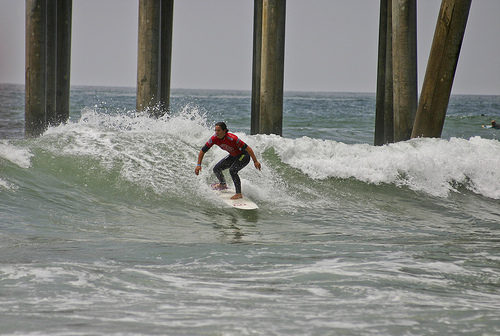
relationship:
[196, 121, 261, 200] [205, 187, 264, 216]
surfer on surfboard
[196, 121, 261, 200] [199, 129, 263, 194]
surfer in wetsuit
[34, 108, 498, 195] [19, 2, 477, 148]
waves under pier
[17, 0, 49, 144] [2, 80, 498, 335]
pole in water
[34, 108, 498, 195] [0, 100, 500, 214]
waves have waves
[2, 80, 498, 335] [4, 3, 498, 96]
water meets sky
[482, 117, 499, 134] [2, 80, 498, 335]
surfer in water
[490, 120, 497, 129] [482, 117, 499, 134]
head of surfer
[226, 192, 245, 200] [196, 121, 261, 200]
foot of surfer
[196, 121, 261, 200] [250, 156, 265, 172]
surfer has hand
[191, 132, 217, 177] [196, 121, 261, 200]
arm of surfer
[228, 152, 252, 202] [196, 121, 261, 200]
leg of surfer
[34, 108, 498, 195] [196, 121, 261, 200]
waves behind surfer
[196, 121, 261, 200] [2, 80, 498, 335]
surfer in water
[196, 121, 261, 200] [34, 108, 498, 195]
surfer riding waves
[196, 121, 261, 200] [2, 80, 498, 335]
surfer in ocean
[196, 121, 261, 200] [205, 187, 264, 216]
surfer on white board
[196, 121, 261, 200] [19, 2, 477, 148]
surfer close to pier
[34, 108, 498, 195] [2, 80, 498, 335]
waves in water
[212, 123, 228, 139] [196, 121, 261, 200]
face of surfer